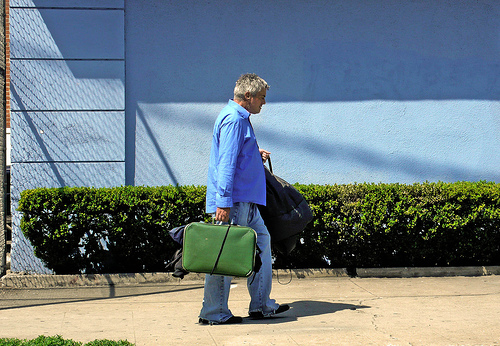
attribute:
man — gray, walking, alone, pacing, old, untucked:
[197, 65, 294, 325]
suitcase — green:
[181, 218, 261, 287]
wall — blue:
[272, 15, 476, 168]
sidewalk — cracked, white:
[28, 290, 371, 331]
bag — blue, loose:
[271, 176, 313, 230]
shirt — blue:
[218, 114, 258, 185]